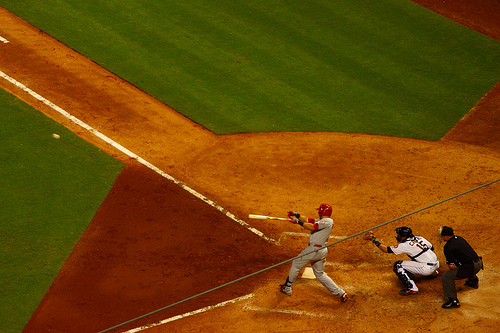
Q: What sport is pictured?
A: Baseball.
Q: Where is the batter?
A: Home plate.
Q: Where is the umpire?
A: Behind the catcher.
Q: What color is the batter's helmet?
A: Red.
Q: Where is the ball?
A: In the air.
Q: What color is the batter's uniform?
A: Grey.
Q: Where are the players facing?
A: Left.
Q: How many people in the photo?
A: 3.